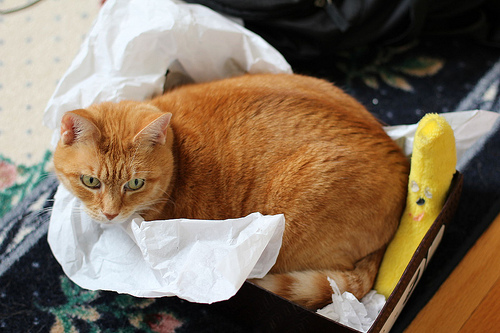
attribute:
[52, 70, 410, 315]
cat — curled up, orange, lying down, sitting, tabby, white, furry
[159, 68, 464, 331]
box — brown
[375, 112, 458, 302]
toy — banana, yellow, fuzzy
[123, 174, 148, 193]
eye — green, yellowish green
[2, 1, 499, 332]
carpet — flower print, floral, blue green, pink, flower design, dotted, flower patterened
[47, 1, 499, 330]
tissue paper — white, scrunched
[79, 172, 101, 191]
eye — green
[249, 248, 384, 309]
tail — stripped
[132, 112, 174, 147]
ear — furry